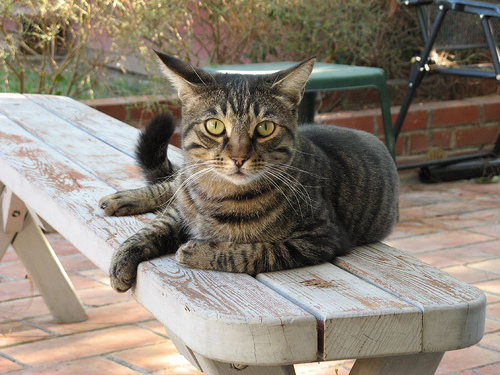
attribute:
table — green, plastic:
[173, 53, 412, 223]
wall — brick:
[282, 95, 483, 177]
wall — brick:
[328, 100, 498, 162]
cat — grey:
[88, 53, 401, 294]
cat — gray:
[114, 55, 394, 278]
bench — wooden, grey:
[18, 82, 488, 372]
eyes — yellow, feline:
[196, 115, 276, 139]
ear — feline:
[269, 55, 318, 108]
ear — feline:
[147, 47, 225, 109]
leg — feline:
[184, 238, 331, 278]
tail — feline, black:
[130, 112, 179, 179]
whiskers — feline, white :
[258, 158, 327, 202]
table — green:
[152, 52, 380, 95]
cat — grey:
[128, 41, 403, 272]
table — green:
[182, 44, 385, 103]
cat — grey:
[138, 49, 418, 262]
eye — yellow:
[253, 114, 284, 142]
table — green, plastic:
[158, 49, 389, 96]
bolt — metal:
[5, 199, 28, 226]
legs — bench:
[5, 188, 84, 321]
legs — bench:
[203, 346, 459, 365]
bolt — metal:
[220, 341, 260, 372]